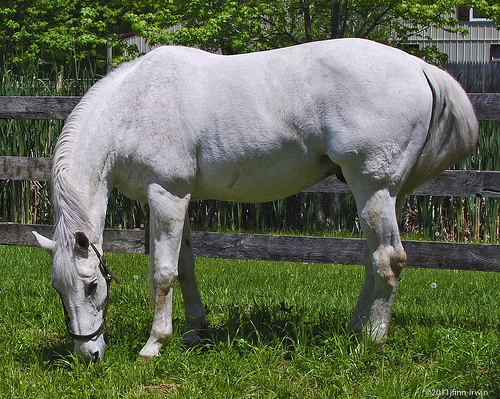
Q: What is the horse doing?
A: Eating grass.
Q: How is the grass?
A: Green and healthy.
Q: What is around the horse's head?
A: Halter.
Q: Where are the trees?
A: Behind the fence.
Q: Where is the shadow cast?
A: Under the horse.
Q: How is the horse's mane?
A: Short.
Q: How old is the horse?
A: Adult.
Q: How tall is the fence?
A: Shorter than the horse.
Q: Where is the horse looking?
A: Down at the ground.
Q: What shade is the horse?
A: White.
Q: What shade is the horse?
A: White.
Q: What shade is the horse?
A: White.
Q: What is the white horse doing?
A: Eating grass.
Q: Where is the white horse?
A: Standing in a field.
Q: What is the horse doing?
A: Eating.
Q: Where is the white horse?
A: By the fence.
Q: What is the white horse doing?
A: Eating grass.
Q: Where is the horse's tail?
A: Between the horse's back legs.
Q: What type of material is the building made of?
A: Corrugated metal.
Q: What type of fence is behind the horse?
A: Wooden.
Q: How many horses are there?
A: 1.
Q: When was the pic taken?
A: During the day.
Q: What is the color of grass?
A: Green.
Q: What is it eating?
A: Grass.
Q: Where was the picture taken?
A: In the field.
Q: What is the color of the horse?
A: White.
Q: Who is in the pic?
A: No one.